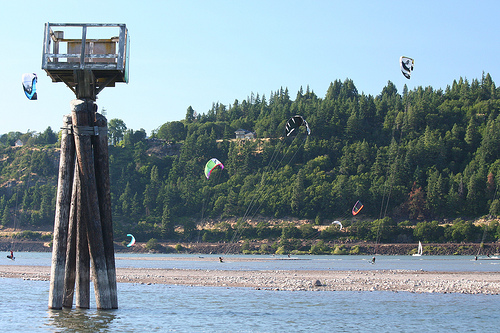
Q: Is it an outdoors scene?
A: Yes, it is outdoors.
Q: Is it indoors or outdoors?
A: It is outdoors.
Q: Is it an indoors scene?
A: No, it is outdoors.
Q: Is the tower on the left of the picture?
A: Yes, the tower is on the left of the image.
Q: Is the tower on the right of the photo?
A: No, the tower is on the left of the image.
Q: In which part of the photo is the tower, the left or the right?
A: The tower is on the left of the image.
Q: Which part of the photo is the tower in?
A: The tower is on the left of the image.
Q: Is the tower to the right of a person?
A: No, the tower is to the left of a person.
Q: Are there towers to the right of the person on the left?
A: Yes, there is a tower to the right of the person.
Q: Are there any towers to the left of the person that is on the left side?
A: No, the tower is to the right of the person.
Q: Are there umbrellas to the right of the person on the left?
A: No, there is a tower to the right of the person.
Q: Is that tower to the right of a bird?
A: No, the tower is to the right of a person.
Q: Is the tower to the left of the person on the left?
A: No, the tower is to the right of the person.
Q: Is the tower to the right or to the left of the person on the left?
A: The tower is to the right of the person.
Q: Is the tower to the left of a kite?
A: Yes, the tower is to the left of a kite.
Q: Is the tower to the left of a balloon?
A: No, the tower is to the left of a kite.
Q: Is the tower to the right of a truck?
A: No, the tower is to the right of the kite.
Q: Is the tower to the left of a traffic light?
A: No, the tower is to the left of the kite.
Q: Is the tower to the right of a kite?
A: No, the tower is to the left of a kite.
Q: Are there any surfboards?
A: No, there are no surfboards.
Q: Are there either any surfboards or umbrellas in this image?
A: No, there are no surfboards or umbrellas.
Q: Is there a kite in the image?
A: Yes, there is a kite.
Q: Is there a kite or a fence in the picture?
A: Yes, there is a kite.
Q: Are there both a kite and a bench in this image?
A: No, there is a kite but no benches.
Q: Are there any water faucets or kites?
A: Yes, there is a water kite.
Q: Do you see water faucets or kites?
A: Yes, there is a water kite.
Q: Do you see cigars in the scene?
A: No, there are no cigars.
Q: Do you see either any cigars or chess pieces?
A: No, there are no cigars or chess pieces.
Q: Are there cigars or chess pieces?
A: No, there are no cigars or chess pieces.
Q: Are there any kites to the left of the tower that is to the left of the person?
A: Yes, there is a kite to the left of the tower.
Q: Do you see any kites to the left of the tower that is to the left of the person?
A: Yes, there is a kite to the left of the tower.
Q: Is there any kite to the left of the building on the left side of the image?
A: Yes, there is a kite to the left of the tower.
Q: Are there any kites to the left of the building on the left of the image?
A: Yes, there is a kite to the left of the tower.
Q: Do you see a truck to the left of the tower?
A: No, there is a kite to the left of the tower.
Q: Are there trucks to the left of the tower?
A: No, there is a kite to the left of the tower.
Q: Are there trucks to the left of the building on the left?
A: No, there is a kite to the left of the tower.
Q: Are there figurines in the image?
A: No, there are no figurines.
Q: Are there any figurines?
A: No, there are no figurines.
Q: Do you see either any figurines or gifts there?
A: No, there are no figurines or gifts.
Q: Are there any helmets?
A: No, there are no helmets.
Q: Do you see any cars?
A: No, there are no cars.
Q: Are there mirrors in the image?
A: No, there are no mirrors.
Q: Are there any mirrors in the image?
A: No, there are no mirrors.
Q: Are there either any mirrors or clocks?
A: No, there are no mirrors or clocks.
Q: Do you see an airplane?
A: No, there are no airplanes.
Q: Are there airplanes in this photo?
A: No, there are no airplanes.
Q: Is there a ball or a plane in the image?
A: No, there are no airplanes or balls.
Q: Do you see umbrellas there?
A: No, there are no umbrellas.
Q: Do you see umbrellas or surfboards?
A: No, there are no umbrellas or surfboards.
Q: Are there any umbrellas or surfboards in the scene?
A: No, there are no umbrellas or surfboards.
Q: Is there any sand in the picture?
A: Yes, there is sand.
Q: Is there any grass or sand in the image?
A: Yes, there is sand.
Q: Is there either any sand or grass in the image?
A: Yes, there is sand.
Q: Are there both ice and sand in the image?
A: No, there is sand but no ice.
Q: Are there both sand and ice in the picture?
A: No, there is sand but no ice.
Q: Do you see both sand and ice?
A: No, there is sand but no ice.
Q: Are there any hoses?
A: No, there are no hoses.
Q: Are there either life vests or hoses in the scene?
A: No, there are no hoses or life vests.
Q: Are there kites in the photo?
A: Yes, there is a kite.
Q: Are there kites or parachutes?
A: Yes, there is a kite.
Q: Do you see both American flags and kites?
A: No, there is a kite but no American flags.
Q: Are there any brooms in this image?
A: No, there are no brooms.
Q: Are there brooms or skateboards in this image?
A: No, there are no brooms or skateboards.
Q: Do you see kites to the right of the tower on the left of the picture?
A: Yes, there is a kite to the right of the tower.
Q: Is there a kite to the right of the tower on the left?
A: Yes, there is a kite to the right of the tower.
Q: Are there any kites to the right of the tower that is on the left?
A: Yes, there is a kite to the right of the tower.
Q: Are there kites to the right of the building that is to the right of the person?
A: Yes, there is a kite to the right of the tower.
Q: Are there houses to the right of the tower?
A: No, there is a kite to the right of the tower.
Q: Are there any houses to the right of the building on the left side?
A: No, there is a kite to the right of the tower.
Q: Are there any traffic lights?
A: No, there are no traffic lights.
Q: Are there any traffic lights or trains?
A: No, there are no traffic lights or trains.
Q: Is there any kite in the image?
A: Yes, there is a kite.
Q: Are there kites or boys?
A: Yes, there is a kite.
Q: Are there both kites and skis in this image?
A: No, there is a kite but no skis.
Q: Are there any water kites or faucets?
A: Yes, there is a water kite.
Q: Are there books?
A: No, there are no books.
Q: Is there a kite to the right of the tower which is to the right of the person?
A: Yes, there is a kite to the right of the tower.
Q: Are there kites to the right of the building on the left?
A: Yes, there is a kite to the right of the tower.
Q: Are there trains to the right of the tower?
A: No, there is a kite to the right of the tower.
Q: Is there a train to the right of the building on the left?
A: No, there is a kite to the right of the tower.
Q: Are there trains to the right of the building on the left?
A: No, there is a kite to the right of the tower.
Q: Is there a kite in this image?
A: Yes, there is a kite.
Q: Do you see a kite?
A: Yes, there is a kite.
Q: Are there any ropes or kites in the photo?
A: Yes, there is a kite.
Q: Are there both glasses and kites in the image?
A: No, there is a kite but no glasses.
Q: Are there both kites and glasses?
A: No, there is a kite but no glasses.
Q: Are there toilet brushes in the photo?
A: No, there are no toilet brushes.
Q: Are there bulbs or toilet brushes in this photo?
A: No, there are no toilet brushes or bulbs.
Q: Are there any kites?
A: Yes, there is a kite.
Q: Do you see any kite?
A: Yes, there is a kite.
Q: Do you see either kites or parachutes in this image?
A: Yes, there is a kite.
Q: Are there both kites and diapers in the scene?
A: No, there is a kite but no diapers.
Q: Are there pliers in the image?
A: No, there are no pliers.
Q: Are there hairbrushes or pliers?
A: No, there are no pliers or hairbrushes.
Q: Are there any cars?
A: No, there are no cars.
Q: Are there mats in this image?
A: No, there are no mats.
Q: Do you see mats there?
A: No, there are no mats.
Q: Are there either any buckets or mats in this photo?
A: No, there are no mats or buckets.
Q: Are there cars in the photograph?
A: No, there are no cars.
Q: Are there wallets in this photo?
A: No, there are no wallets.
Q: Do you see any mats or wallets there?
A: No, there are no wallets or mats.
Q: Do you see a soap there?
A: No, there are no soaps.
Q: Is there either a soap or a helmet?
A: No, there are no soaps or helmets.